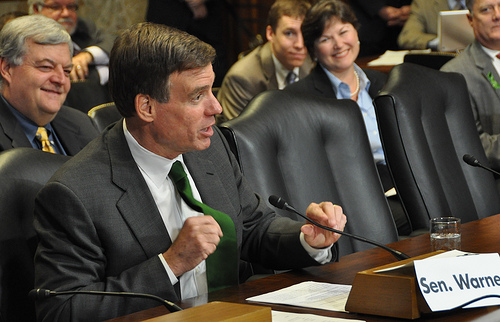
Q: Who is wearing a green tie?
A: A man.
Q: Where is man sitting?
A: Long table.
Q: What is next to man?
A: Empty chair.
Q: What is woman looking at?
A: The man.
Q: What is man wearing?
A: Grey suit.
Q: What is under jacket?
A: White shirt.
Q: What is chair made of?
A: Leather.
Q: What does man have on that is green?
A: Tie.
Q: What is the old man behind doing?
A: Smiling.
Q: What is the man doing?
A: Giving a speech.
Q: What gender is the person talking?
A: Male.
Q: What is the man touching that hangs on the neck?
A: Tie.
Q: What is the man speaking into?
A: Microphone.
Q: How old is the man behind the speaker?
A: Old.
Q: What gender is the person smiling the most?
A: Female.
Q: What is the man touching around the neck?
A: Tie.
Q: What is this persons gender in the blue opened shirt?
A: Female.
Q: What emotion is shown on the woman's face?
A: Happiness.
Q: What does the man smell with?
A: Nose.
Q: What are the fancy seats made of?
A: Leather.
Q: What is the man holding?
A: Neck tie.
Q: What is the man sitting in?
A: Chair.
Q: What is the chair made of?
A: Leather.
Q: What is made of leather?
A: Chair.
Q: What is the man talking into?
A: Microphone.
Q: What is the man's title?
A: Senator.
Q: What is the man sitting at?
A: Table.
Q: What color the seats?
A: Black.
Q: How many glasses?
A: One.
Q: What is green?
A: Tie.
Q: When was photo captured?
A: During meeting.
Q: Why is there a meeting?
A: Congress.